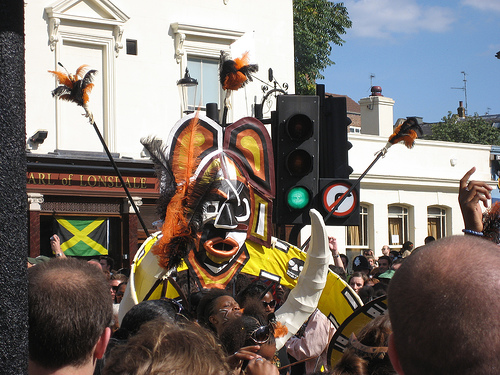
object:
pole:
[279, 225, 300, 248]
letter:
[87, 174, 97, 186]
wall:
[25, 0, 301, 275]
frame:
[168, 22, 245, 119]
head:
[386, 233, 500, 374]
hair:
[387, 233, 500, 374]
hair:
[22, 256, 112, 367]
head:
[26, 259, 114, 370]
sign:
[320, 181, 355, 216]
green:
[287, 187, 308, 209]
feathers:
[47, 69, 69, 85]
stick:
[82, 104, 150, 236]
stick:
[221, 89, 230, 124]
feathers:
[217, 50, 258, 90]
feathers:
[388, 116, 420, 149]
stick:
[300, 143, 392, 248]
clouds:
[329, 0, 499, 39]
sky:
[314, 0, 499, 122]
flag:
[50, 219, 108, 256]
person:
[48, 233, 68, 258]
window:
[200, 58, 219, 109]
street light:
[321, 97, 354, 177]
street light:
[274, 93, 319, 225]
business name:
[26, 172, 147, 188]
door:
[38, 211, 120, 273]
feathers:
[239, 64, 258, 73]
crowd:
[27, 48, 500, 374]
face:
[194, 177, 254, 265]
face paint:
[213, 307, 231, 321]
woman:
[197, 287, 242, 338]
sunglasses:
[250, 320, 275, 342]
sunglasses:
[262, 300, 276, 306]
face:
[259, 290, 274, 316]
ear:
[93, 326, 111, 361]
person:
[117, 112, 364, 339]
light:
[286, 187, 308, 209]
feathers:
[400, 115, 418, 131]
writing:
[79, 174, 147, 187]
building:
[22, 0, 296, 304]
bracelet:
[460, 228, 483, 234]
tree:
[291, 0, 352, 95]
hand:
[457, 166, 492, 233]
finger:
[458, 167, 476, 192]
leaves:
[323, 76, 325, 79]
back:
[28, 257, 112, 362]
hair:
[102, 310, 240, 373]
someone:
[104, 313, 237, 374]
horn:
[272, 208, 328, 351]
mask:
[193, 150, 252, 261]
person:
[242, 280, 290, 373]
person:
[27, 256, 112, 374]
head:
[222, 314, 276, 369]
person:
[387, 232, 499, 373]